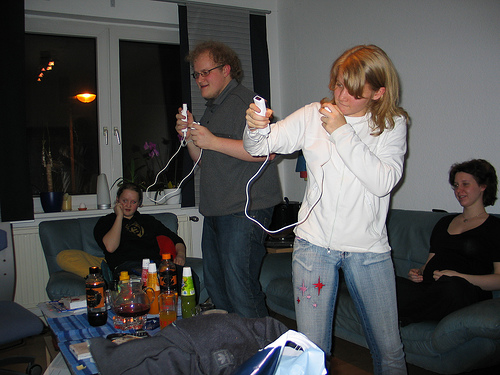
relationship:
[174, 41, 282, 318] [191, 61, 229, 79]
man wearing glasses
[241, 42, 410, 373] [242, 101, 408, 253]
woman wearing a shirt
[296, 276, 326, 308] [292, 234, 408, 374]
design on jeans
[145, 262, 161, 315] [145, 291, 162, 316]
bottle has orange liquid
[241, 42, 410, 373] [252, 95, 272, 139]
woman holding wiimote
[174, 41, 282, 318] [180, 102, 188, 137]
man holding wiimote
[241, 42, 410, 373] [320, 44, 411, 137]
woman has blonde hair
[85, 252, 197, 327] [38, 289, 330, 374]
bottles on coffee table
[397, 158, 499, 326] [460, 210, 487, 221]
lady wearing a necklace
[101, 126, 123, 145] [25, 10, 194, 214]
handles on window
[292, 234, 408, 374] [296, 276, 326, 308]
jeans have a design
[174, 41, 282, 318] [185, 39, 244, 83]
man has hair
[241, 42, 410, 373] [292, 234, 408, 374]
woman wearing jeans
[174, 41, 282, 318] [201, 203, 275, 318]
man wearing jeans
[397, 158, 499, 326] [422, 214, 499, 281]
lady wearing a top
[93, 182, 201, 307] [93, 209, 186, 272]
girl wearing a shirt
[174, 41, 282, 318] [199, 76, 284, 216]
man wearing a shirt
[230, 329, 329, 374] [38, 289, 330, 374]
plastic bag on coffee table